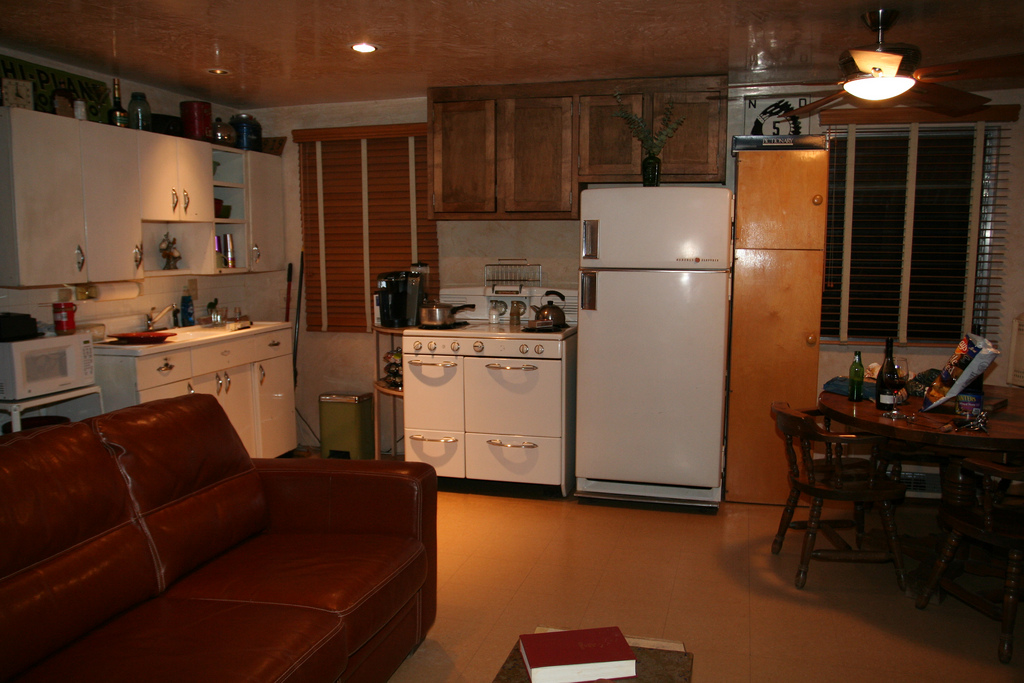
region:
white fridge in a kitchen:
[568, 179, 736, 516]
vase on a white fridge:
[640, 148, 666, 186]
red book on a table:
[511, 617, 641, 679]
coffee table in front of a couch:
[486, 609, 706, 680]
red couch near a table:
[9, 385, 458, 680]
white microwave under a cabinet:
[5, 325, 101, 403]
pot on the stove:
[414, 291, 478, 333]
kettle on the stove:
[524, 287, 573, 326]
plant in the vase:
[594, 78, 687, 154]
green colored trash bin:
[316, 383, 377, 470]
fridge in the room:
[443, 130, 804, 501]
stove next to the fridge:
[375, 284, 591, 434]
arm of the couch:
[268, 411, 462, 535]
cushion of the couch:
[189, 468, 411, 636]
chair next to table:
[707, 377, 913, 580]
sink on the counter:
[105, 270, 208, 363]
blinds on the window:
[241, 93, 461, 357]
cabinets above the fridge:
[370, 60, 745, 254]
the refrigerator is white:
[550, 163, 738, 515]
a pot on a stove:
[403, 287, 486, 341]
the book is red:
[495, 607, 705, 678]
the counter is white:
[106, 299, 310, 461]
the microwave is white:
[0, 320, 109, 415]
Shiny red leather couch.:
[2, 386, 446, 674]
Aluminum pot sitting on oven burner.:
[419, 297, 480, 333]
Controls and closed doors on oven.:
[404, 331, 570, 490]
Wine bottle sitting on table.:
[869, 329, 905, 415]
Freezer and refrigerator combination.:
[563, 176, 741, 519]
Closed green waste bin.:
[318, 386, 375, 459]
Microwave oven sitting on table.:
[3, 328, 105, 428]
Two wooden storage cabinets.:
[724, 145, 832, 507]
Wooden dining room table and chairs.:
[771, 329, 1022, 628]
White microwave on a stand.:
[9, 300, 105, 414]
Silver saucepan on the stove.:
[409, 288, 492, 330]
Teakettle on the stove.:
[523, 277, 568, 338]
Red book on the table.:
[505, 609, 655, 679]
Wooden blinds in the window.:
[293, 97, 446, 339]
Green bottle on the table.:
[833, 337, 872, 411]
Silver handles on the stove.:
[399, 356, 542, 377]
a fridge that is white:
[582, 223, 723, 489]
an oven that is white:
[409, 331, 556, 478]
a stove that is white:
[444, 287, 559, 341]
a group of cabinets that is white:
[128, 318, 310, 449]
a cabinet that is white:
[13, 113, 137, 278]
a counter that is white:
[185, 298, 255, 340]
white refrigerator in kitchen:
[557, 167, 739, 515]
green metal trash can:
[310, 380, 384, 463]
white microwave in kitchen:
[1, 322, 101, 405]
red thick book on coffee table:
[504, 616, 644, 680]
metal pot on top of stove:
[411, 290, 482, 330]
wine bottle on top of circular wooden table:
[867, 332, 903, 421]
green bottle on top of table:
[842, 344, 872, 409]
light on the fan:
[795, 38, 972, 133]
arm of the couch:
[223, 411, 499, 544]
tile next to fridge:
[473, 508, 607, 606]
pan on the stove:
[388, 269, 507, 352]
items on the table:
[796, 298, 1022, 477]